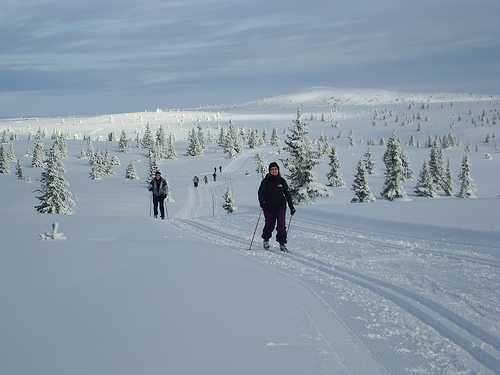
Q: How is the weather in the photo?
A: It is cloudy.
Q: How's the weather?
A: It is cloudy.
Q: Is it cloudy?
A: Yes, it is cloudy.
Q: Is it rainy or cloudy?
A: It is cloudy.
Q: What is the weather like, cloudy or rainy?
A: It is cloudy.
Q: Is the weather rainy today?
A: No, it is cloudy.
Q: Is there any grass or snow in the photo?
A: Yes, there is snow.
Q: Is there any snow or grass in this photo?
A: Yes, there is snow.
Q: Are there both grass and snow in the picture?
A: No, there is snow but no grass.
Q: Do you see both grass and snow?
A: No, there is snow but no grass.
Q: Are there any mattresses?
A: No, there are no mattresses.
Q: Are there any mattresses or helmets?
A: No, there are no mattresses or helmets.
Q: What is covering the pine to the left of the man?
A: The snow is covering the pine.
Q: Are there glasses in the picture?
A: No, there are no glasses.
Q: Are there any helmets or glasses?
A: No, there are no glasses or helmets.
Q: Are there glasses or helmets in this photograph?
A: No, there are no glasses or helmets.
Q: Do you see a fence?
A: No, there are no fences.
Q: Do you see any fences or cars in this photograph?
A: No, there are no fences or cars.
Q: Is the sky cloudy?
A: Yes, the sky is cloudy.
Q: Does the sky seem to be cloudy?
A: Yes, the sky is cloudy.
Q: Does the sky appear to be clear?
A: No, the sky is cloudy.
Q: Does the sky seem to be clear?
A: No, the sky is cloudy.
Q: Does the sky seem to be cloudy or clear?
A: The sky is cloudy.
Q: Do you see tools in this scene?
A: No, there are no tools.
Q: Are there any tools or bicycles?
A: No, there are no tools or bicycles.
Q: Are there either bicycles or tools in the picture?
A: No, there are no tools or bicycles.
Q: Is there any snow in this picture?
A: Yes, there is snow.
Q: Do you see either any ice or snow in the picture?
A: Yes, there is snow.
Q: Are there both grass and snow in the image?
A: No, there is snow but no grass.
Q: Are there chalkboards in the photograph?
A: No, there are no chalkboards.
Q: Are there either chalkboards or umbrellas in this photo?
A: No, there are no chalkboards or umbrellas.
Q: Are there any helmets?
A: No, there are no helmets.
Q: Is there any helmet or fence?
A: No, there are no helmets or fences.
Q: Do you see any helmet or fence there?
A: No, there are no helmets or fences.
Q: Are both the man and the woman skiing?
A: Yes, both the man and the woman are skiing.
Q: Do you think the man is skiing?
A: Yes, the man is skiing.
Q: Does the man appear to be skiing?
A: Yes, the man is skiing.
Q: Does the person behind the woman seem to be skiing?
A: Yes, the man is skiing.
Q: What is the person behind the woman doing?
A: The man is skiing.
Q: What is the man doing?
A: The man is skiing.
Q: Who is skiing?
A: The man is skiing.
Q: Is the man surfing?
A: No, the man is skiing.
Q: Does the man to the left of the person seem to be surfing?
A: No, the man is skiing.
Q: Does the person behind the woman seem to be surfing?
A: No, the man is skiing.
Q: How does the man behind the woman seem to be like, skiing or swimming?
A: The man is skiing.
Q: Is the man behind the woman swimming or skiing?
A: The man is skiing.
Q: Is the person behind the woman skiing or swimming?
A: The man is skiing.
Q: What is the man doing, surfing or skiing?
A: The man is skiing.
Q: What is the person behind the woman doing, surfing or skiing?
A: The man is skiing.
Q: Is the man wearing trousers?
A: Yes, the man is wearing trousers.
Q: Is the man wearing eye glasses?
A: No, the man is wearing trousers.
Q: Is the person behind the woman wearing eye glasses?
A: No, the man is wearing trousers.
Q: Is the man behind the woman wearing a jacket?
A: Yes, the man is wearing a jacket.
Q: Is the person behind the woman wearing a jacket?
A: Yes, the man is wearing a jacket.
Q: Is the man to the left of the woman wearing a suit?
A: No, the man is wearing a jacket.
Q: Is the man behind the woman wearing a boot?
A: Yes, the man is wearing a boot.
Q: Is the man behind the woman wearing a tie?
A: No, the man is wearing a boot.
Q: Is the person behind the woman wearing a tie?
A: No, the man is wearing a boot.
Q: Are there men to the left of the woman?
A: Yes, there is a man to the left of the woman.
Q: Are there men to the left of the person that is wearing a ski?
A: Yes, there is a man to the left of the woman.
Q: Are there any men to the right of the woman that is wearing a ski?
A: No, the man is to the left of the woman.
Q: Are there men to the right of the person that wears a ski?
A: No, the man is to the left of the woman.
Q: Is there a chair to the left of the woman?
A: No, there is a man to the left of the woman.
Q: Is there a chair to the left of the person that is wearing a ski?
A: No, there is a man to the left of the woman.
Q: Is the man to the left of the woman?
A: Yes, the man is to the left of the woman.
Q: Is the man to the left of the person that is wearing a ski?
A: Yes, the man is to the left of the woman.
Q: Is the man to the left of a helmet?
A: No, the man is to the left of the woman.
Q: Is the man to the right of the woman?
A: No, the man is to the left of the woman.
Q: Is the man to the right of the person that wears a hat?
A: No, the man is to the left of the woman.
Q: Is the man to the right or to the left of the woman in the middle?
A: The man is to the left of the woman.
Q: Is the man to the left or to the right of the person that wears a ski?
A: The man is to the left of the woman.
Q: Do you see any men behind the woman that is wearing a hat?
A: Yes, there is a man behind the woman.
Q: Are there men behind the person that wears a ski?
A: Yes, there is a man behind the woman.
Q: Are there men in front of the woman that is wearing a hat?
A: No, the man is behind the woman.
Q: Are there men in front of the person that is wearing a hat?
A: No, the man is behind the woman.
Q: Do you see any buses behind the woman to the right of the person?
A: No, there is a man behind the woman.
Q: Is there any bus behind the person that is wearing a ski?
A: No, there is a man behind the woman.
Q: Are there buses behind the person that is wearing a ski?
A: No, there is a man behind the woman.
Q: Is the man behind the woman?
A: Yes, the man is behind the woman.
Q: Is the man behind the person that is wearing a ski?
A: Yes, the man is behind the woman.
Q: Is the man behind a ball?
A: No, the man is behind the woman.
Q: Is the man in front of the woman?
A: No, the man is behind the woman.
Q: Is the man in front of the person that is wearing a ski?
A: No, the man is behind the woman.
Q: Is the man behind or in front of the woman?
A: The man is behind the woman.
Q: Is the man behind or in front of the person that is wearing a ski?
A: The man is behind the woman.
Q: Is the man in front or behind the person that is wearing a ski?
A: The man is behind the woman.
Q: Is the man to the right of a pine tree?
A: Yes, the man is to the right of a pine tree.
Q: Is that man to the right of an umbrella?
A: No, the man is to the right of a pine tree.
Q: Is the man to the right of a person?
A: No, the man is to the left of a person.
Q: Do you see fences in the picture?
A: No, there are no fences.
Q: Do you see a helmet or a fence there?
A: No, there are no fences or helmets.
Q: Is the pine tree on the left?
A: Yes, the pine tree is on the left of the image.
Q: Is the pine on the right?
A: No, the pine is on the left of the image.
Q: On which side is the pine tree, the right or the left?
A: The pine tree is on the left of the image.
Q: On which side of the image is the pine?
A: The pine is on the left of the image.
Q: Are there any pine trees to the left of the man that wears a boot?
A: Yes, there is a pine tree to the left of the man.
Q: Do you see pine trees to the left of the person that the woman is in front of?
A: Yes, there is a pine tree to the left of the man.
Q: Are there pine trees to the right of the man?
A: No, the pine tree is to the left of the man.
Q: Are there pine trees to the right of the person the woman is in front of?
A: No, the pine tree is to the left of the man.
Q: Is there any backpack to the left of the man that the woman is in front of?
A: No, there is a pine tree to the left of the man.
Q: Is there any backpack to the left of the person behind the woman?
A: No, there is a pine tree to the left of the man.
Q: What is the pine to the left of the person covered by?
A: The pine tree is covered by the snow.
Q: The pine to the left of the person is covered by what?
A: The pine tree is covered by the snow.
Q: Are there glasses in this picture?
A: No, there are no glasses.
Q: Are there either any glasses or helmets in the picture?
A: No, there are no glasses or helmets.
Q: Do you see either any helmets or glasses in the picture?
A: No, there are no glasses or helmets.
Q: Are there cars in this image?
A: No, there are no cars.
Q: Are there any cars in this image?
A: No, there are no cars.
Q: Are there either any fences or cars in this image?
A: No, there are no cars or fences.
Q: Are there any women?
A: Yes, there is a woman.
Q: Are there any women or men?
A: Yes, there is a woman.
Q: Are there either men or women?
A: Yes, there is a woman.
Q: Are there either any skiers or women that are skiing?
A: Yes, the woman is skiing.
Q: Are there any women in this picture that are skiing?
A: Yes, there is a woman that is skiing.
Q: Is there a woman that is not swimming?
A: Yes, there is a woman that is skiing.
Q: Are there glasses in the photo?
A: No, there are no glasses.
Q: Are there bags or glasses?
A: No, there are no glasses or bags.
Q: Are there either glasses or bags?
A: No, there are no glasses or bags.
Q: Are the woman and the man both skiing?
A: Yes, both the woman and the man are skiing.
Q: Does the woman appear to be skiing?
A: Yes, the woman is skiing.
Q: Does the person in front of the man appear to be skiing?
A: Yes, the woman is skiing.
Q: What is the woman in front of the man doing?
A: The woman is skiing.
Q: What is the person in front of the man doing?
A: The woman is skiing.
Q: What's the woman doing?
A: The woman is skiing.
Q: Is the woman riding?
A: No, the woman is skiing.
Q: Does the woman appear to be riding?
A: No, the woman is skiing.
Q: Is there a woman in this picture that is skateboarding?
A: No, there is a woman but she is skiing.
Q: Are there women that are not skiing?
A: No, there is a woman but she is skiing.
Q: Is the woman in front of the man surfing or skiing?
A: The woman is skiing.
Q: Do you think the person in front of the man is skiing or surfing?
A: The woman is skiing.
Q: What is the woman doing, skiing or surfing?
A: The woman is skiing.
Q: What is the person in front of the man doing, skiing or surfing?
A: The woman is skiing.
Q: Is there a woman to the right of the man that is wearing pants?
A: Yes, there is a woman to the right of the man.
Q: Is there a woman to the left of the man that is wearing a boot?
A: No, the woman is to the right of the man.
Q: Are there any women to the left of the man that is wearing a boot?
A: No, the woman is to the right of the man.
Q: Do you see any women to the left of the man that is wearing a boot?
A: No, the woman is to the right of the man.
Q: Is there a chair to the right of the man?
A: No, there is a woman to the right of the man.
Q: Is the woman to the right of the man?
A: Yes, the woman is to the right of the man.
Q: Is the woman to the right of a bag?
A: No, the woman is to the right of the man.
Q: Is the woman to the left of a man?
A: No, the woman is to the right of a man.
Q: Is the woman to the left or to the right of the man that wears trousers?
A: The woman is to the right of the man.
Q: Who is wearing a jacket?
A: The woman is wearing a jacket.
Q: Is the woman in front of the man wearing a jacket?
A: Yes, the woman is wearing a jacket.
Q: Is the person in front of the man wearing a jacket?
A: Yes, the woman is wearing a jacket.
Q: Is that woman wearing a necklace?
A: No, the woman is wearing a jacket.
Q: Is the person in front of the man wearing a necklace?
A: No, the woman is wearing a jacket.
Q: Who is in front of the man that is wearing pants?
A: The woman is in front of the man.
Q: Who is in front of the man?
A: The woman is in front of the man.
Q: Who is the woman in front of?
A: The woman is in front of the man.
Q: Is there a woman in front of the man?
A: Yes, there is a woman in front of the man.